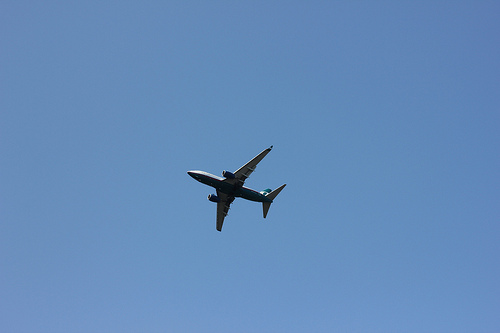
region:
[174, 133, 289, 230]
airplane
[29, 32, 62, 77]
white clouds in blue sky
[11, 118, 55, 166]
white clouds in blue sky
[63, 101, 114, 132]
white clouds in blue sky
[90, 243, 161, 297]
white clouds in blue sky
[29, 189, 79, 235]
white clouds in blue sky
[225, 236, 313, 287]
white clouds in blue sky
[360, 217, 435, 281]
white clouds in blue sky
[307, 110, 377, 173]
white clouds in blue sky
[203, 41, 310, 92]
white clouds in blue sky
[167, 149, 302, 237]
silver plane in sky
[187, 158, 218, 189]
silver tip on plane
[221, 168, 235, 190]
silver engine on plane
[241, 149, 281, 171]
silver wing on plane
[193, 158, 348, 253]
plane in blue sky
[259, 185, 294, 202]
silver tail on plane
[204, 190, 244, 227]
silver wing on plane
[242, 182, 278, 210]
silver body on plane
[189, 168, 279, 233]
silver bottom on plane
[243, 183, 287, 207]
silver top on plane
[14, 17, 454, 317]
a plane in the air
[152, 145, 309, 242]
this plane is flying solo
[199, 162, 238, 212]
this is a twin engine plane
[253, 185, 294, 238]
this is the tail of the plane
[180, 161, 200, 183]
this is the nose of the plane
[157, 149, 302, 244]
this plane transports passengers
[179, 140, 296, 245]
this plane transports cargo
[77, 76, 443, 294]
the plane is flying in clear skies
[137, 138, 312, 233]
the plane is gray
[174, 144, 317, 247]
this is a shot taken from underneath the plane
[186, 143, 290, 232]
plane soaring in the sky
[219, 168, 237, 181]
engine on a plane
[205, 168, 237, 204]
two engines on a plane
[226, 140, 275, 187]
wing of a plane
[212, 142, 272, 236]
two wings of a plane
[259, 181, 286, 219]
tail of a plane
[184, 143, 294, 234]
single plane flying in the sky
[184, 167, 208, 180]
nose of a plane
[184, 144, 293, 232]
bottom of a large plane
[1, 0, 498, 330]
plane flying in a clear blue sky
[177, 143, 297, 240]
Commercial airplane in the sky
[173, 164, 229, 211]
Commercial airplane in the sky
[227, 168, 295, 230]
Commercial airplane in the sky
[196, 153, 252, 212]
Two engines on a plane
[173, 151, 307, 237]
Jumbo jet soaring through the sky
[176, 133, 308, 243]
Plane in the sky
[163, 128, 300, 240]
Plane going through the sky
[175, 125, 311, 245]
Plane flying in the air